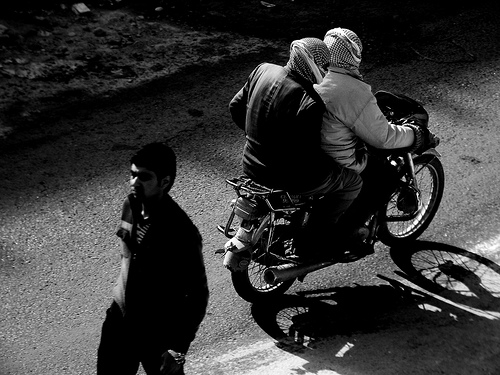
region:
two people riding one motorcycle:
[207, 20, 463, 295]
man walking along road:
[82, 126, 222, 362]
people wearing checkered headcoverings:
[275, 25, 385, 95]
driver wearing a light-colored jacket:
[311, 17, 427, 193]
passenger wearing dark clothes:
[230, 36, 356, 257]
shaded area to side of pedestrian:
[15, 11, 220, 208]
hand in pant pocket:
[85, 280, 210, 370]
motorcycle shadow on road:
[246, 236, 486, 356]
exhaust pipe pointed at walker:
[110, 151, 300, 346]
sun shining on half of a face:
[88, 137, 185, 213]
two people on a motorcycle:
[212, 23, 449, 308]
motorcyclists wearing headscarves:
[222, 23, 433, 265]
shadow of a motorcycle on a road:
[247, 236, 498, 371]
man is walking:
[87, 138, 214, 374]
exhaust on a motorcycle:
[257, 248, 369, 285]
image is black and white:
[3, 3, 495, 369]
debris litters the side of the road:
[5, 3, 277, 115]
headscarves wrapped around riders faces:
[284, 22, 369, 90]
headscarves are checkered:
[284, 23, 364, 88]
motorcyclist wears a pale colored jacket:
[310, 24, 416, 250]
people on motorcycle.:
[215, 33, 487, 310]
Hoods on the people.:
[251, 22, 388, 112]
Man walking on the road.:
[73, 97, 263, 373]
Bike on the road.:
[230, 50, 490, 354]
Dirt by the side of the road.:
[51, 22, 206, 97]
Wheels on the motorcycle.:
[360, 117, 475, 277]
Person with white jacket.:
[335, 39, 402, 143]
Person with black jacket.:
[256, 51, 348, 190]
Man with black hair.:
[101, 113, 218, 245]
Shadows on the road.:
[403, 250, 485, 314]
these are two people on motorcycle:
[210, 20, 437, 290]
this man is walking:
[90, 148, 205, 364]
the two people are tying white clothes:
[287, 26, 358, 80]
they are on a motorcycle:
[277, 193, 423, 259]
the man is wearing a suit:
[230, 76, 313, 178]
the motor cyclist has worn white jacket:
[330, 80, 368, 154]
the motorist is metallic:
[227, 189, 279, 293]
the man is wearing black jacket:
[109, 208, 201, 328]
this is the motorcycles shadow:
[292, 281, 479, 374]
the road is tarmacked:
[0, 166, 83, 352]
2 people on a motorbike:
[183, 35, 451, 295]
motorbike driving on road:
[119, 49, 463, 364]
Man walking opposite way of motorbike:
[99, 132, 266, 364]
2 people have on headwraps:
[228, 33, 390, 83]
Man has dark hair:
[88, 111, 207, 225]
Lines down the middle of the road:
[171, 321, 439, 371]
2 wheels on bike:
[207, 186, 496, 271]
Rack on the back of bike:
[216, 135, 306, 272]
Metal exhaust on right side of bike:
[259, 257, 341, 287]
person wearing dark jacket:
[240, 37, 330, 188]